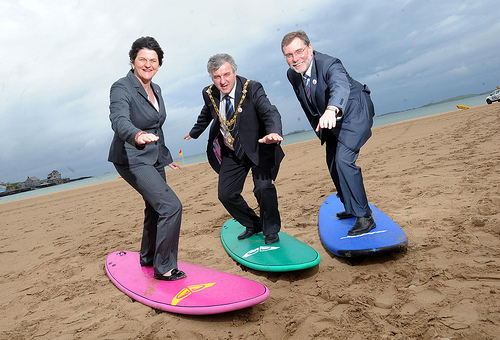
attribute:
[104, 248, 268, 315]
surfboard — pink, yellow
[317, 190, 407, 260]
surfboard — blue, white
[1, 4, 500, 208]
clouds in sky — white, blue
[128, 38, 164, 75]
woman has hair — very short